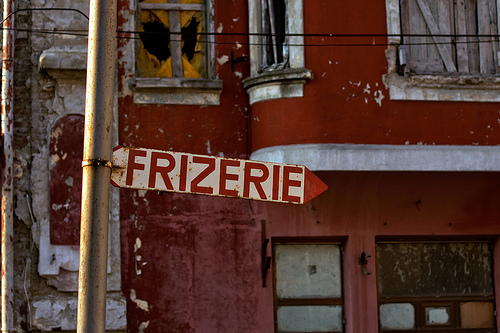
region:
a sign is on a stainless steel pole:
[80, 116, 330, 217]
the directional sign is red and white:
[103, 139, 329, 212]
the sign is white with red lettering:
[98, 138, 323, 216]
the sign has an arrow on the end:
[129, 145, 331, 207]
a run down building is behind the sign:
[8, 4, 493, 327]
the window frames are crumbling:
[388, 8, 498, 103]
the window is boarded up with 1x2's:
[383, 0, 498, 93]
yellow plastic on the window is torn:
[131, 5, 217, 90]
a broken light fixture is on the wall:
[351, 245, 375, 280]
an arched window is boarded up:
[40, 100, 117, 278]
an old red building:
[6, 0, 496, 325]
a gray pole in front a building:
[57, 0, 129, 330]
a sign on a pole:
[73, 133, 338, 213]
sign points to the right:
[85, 138, 337, 218]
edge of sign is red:
[97, 141, 335, 211]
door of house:
[260, 226, 352, 331]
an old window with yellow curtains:
[115, 6, 241, 109]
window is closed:
[384, 6, 499, 104]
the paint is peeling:
[106, 200, 225, 332]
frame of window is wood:
[115, 2, 230, 109]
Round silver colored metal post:
[72, 0, 115, 332]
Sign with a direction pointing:
[83, 142, 336, 212]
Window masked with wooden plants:
[385, 0, 499, 95]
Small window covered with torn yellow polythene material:
[130, 4, 217, 86]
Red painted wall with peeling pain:
[121, 0, 498, 332]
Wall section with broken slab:
[1, 0, 133, 332]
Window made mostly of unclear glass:
[365, 230, 498, 326]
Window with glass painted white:
[265, 235, 345, 330]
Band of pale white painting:
[249, 140, 499, 173]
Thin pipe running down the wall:
[0, 0, 18, 332]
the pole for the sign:
[77, 0, 119, 332]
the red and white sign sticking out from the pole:
[110, 144, 328, 204]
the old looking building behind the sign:
[0, 0, 498, 332]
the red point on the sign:
[304, 167, 327, 202]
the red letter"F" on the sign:
[122, 149, 145, 186]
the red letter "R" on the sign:
[145, 151, 175, 190]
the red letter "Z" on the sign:
[191, 154, 216, 193]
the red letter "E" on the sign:
[218, 157, 240, 195]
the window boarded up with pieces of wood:
[385, 1, 498, 101]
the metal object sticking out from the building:
[357, 249, 372, 276]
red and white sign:
[120, 137, 315, 217]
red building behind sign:
[199, 16, 463, 330]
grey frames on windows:
[131, 66, 322, 98]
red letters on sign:
[127, 145, 304, 208]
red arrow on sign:
[302, 163, 324, 207]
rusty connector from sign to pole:
[82, 151, 121, 178]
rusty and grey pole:
[72, 7, 112, 312]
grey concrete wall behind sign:
[247, 126, 499, 208]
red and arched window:
[50, 126, 100, 247]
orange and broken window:
[136, 0, 203, 77]